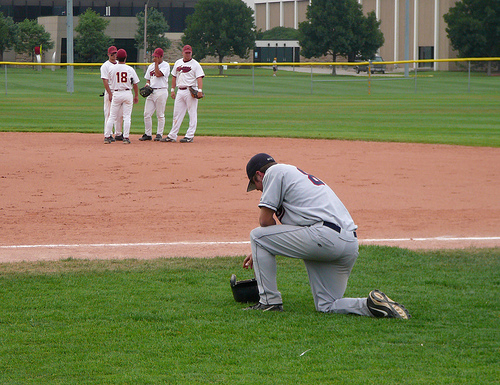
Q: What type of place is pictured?
A: It is a field.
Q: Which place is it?
A: It is a field.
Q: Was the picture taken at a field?
A: Yes, it was taken in a field.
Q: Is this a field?
A: Yes, it is a field.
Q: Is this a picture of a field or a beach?
A: It is showing a field.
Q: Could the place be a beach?
A: No, it is a field.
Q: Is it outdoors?
A: Yes, it is outdoors.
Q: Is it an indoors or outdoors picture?
A: It is outdoors.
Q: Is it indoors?
A: No, it is outdoors.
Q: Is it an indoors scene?
A: No, it is outdoors.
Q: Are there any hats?
A: Yes, there is a hat.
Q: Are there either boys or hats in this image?
A: Yes, there is a hat.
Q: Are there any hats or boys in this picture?
A: Yes, there is a hat.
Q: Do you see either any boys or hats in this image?
A: Yes, there is a hat.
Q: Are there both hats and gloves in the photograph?
A: Yes, there are both a hat and gloves.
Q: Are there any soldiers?
A: No, there are no soldiers.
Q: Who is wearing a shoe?
A: The player is wearing a shoe.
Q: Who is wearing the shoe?
A: The player is wearing a shoe.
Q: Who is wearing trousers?
A: The player is wearing trousers.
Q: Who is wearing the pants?
A: The player is wearing trousers.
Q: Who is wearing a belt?
A: The player is wearing a belt.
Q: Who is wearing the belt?
A: The player is wearing a belt.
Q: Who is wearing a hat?
A: The player is wearing a hat.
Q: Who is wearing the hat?
A: The player is wearing a hat.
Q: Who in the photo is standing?
A: The player is standing.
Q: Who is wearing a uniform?
A: The player is wearing a uniform.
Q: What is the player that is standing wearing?
A: The player is wearing a uniform.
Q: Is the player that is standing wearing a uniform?
A: Yes, the player is wearing a uniform.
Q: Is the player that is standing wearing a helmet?
A: No, the player is wearing a uniform.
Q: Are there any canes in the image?
A: No, there are no canes.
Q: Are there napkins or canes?
A: No, there are no canes or napkins.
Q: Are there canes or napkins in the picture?
A: No, there are no canes or napkins.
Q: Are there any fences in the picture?
A: Yes, there is a fence.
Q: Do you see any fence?
A: Yes, there is a fence.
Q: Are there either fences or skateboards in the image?
A: Yes, there is a fence.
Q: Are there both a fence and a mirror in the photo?
A: No, there is a fence but no mirrors.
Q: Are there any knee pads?
A: No, there are no knee pads.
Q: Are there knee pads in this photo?
A: No, there are no knee pads.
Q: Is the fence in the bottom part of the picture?
A: No, the fence is in the top of the image.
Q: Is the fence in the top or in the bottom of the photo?
A: The fence is in the top of the image.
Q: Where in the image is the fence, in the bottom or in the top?
A: The fence is in the top of the image.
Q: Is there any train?
A: No, there are no trains.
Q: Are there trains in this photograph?
A: No, there are no trains.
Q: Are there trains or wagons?
A: No, there are no trains or wagons.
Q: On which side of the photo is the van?
A: The van is on the right of the image.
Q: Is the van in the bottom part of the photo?
A: No, the van is in the top of the image.